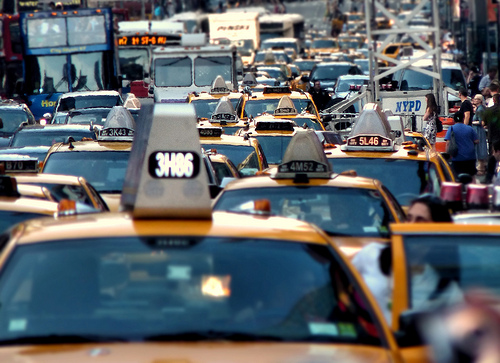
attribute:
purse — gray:
[442, 121, 463, 164]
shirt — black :
[306, 83, 337, 117]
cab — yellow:
[4, 199, 494, 361]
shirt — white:
[351, 246, 459, 321]